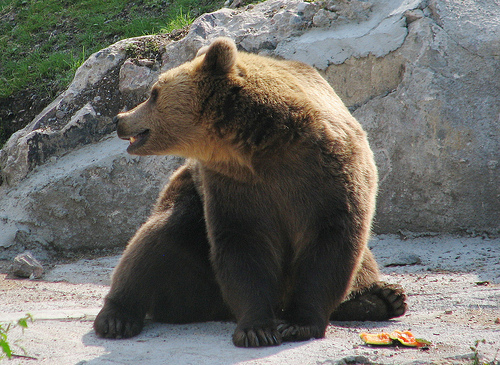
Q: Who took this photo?
A: A tourist.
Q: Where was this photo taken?
A: The zoo.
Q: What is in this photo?
A: A bear.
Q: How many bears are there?
A: One.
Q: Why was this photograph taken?
A: For a magazine.